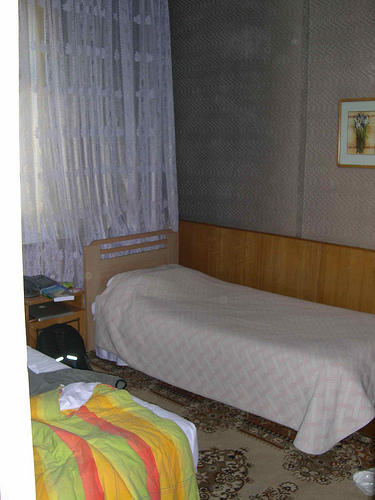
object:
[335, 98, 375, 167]
portrait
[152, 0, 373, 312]
wall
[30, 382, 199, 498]
bedspread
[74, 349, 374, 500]
carpet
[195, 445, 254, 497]
design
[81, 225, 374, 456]
bed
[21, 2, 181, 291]
curtain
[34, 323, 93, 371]
bag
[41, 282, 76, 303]
book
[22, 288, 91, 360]
table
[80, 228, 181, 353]
headboard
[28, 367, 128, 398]
blanket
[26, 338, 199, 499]
bed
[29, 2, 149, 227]
window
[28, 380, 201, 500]
sheet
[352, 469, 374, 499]
object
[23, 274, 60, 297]
phone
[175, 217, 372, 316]
paneling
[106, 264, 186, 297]
pillow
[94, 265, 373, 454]
spread